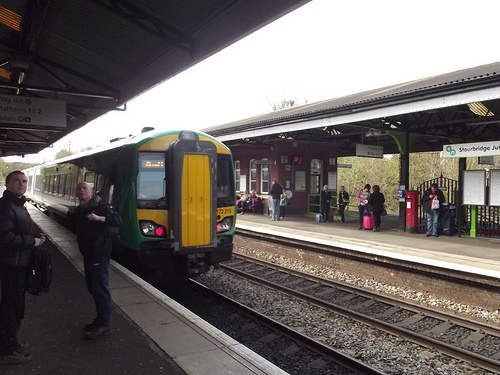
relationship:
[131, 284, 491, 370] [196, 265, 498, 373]
set of track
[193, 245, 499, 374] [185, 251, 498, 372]
ballast on railway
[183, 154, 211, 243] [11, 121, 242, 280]
color on train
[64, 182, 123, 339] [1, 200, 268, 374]
man on platform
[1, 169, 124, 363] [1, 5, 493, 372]
two men standing in station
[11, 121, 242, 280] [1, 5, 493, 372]
train in station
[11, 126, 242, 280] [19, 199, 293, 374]
train boarding platform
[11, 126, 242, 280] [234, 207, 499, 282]
train boarding platform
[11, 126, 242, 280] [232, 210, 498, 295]
train boarding platform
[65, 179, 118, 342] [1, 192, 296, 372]
man on platform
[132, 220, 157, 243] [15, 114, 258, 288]
light on train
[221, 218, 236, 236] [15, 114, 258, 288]
light on train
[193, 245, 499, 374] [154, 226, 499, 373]
ballast on tracks